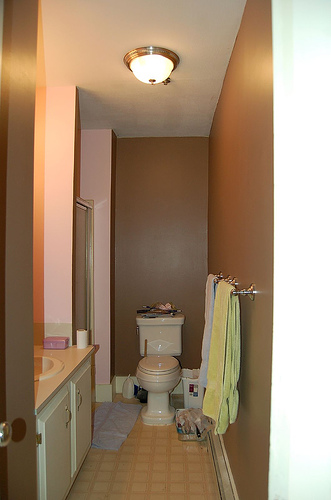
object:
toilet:
[137, 314, 179, 427]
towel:
[205, 288, 243, 430]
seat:
[136, 367, 179, 377]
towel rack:
[241, 287, 259, 298]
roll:
[76, 329, 88, 350]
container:
[44, 339, 72, 351]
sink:
[30, 354, 53, 375]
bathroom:
[75, 81, 269, 496]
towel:
[197, 279, 215, 388]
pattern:
[112, 466, 128, 482]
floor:
[143, 464, 211, 490]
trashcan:
[182, 378, 202, 406]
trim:
[213, 450, 227, 495]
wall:
[208, 118, 274, 269]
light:
[128, 55, 174, 90]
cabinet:
[36, 408, 74, 490]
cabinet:
[72, 372, 94, 467]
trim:
[44, 322, 61, 331]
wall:
[38, 175, 72, 321]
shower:
[85, 212, 92, 329]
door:
[76, 210, 88, 332]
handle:
[66, 408, 70, 424]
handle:
[78, 390, 83, 409]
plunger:
[137, 389, 149, 402]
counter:
[65, 348, 81, 365]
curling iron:
[149, 310, 173, 315]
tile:
[143, 436, 157, 447]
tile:
[81, 485, 90, 492]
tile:
[143, 447, 153, 455]